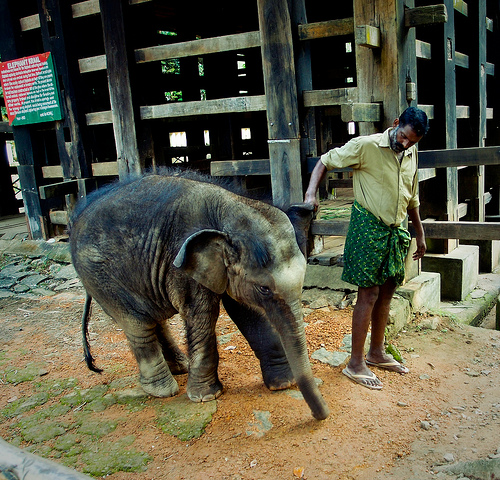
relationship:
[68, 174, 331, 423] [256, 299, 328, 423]
elephant has trunk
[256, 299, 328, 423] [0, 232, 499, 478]
trunk touching ground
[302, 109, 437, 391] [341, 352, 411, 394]
man wearing flip flops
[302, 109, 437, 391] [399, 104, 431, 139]
man has hair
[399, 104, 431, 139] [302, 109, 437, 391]
hair black man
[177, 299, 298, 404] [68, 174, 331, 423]
legs on elephant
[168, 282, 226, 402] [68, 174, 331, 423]
leg on elephant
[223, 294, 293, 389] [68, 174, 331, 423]
leg on elephant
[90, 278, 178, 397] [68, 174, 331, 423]
leg on elephant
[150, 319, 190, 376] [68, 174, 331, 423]
leg on elephant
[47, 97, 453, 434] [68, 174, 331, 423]
man with elephant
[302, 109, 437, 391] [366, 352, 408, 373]
man wearing flip flop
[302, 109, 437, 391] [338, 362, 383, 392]
man wearing flip flop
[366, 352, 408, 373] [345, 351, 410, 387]
flip flop on feet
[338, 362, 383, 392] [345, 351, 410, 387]
flip flop on feet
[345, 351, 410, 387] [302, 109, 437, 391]
feet on man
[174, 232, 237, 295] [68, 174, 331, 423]
ear on elephant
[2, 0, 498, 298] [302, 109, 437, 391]
structure behind man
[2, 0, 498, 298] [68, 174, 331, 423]
structure behind elephant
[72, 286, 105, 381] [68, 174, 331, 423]
tail on elephant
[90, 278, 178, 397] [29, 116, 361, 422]
leg on elepant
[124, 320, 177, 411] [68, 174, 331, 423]
back leg on elephant